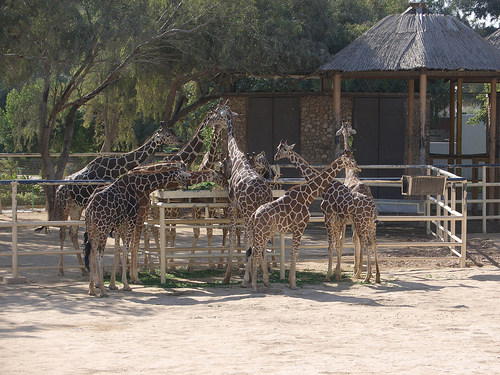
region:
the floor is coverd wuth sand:
[310, 304, 410, 349]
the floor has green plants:
[161, 248, 243, 288]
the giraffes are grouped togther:
[242, 174, 331, 221]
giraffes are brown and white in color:
[215, 162, 362, 225]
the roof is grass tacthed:
[398, 11, 465, 58]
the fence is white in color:
[405, 174, 465, 259]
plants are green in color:
[94, 21, 188, 82]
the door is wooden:
[362, 107, 410, 162]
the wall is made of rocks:
[307, 99, 339, 134]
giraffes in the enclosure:
[30, 124, 407, 299]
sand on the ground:
[185, 318, 346, 360]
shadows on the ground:
[0, 260, 90, 345]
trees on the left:
[9, 12, 190, 124]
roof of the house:
[330, 0, 463, 67]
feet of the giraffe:
[318, 265, 378, 285]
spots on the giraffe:
[331, 197, 362, 222]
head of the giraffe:
[315, 108, 365, 146]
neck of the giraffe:
[225, 127, 252, 168]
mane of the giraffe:
[130, 163, 178, 173]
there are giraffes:
[40, 90, 431, 305]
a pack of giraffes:
[50, 82, 424, 307]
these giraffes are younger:
[245, 119, 380, 290]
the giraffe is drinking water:
[73, 152, 208, 315]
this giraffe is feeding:
[188, 82, 296, 287]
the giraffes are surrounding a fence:
[27, 64, 448, 334]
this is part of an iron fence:
[362, 154, 479, 269]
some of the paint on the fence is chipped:
[4, 168, 120, 205]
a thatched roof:
[325, 3, 499, 75]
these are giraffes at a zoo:
[47, 71, 446, 301]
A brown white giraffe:
[92, 150, 201, 292]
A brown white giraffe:
[250, 137, 375, 279]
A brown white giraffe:
[210, 106, 267, 213]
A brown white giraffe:
[61, 103, 183, 195]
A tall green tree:
[10, 3, 106, 182]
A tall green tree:
[165, 0, 310, 85]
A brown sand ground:
[374, 273, 452, 373]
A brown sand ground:
[219, 292, 319, 347]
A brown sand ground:
[33, 299, 157, 356]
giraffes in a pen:
[12, 21, 482, 333]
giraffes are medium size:
[243, 116, 393, 293]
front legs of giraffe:
[287, 231, 304, 293]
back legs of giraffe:
[247, 235, 272, 292]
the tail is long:
[243, 210, 258, 264]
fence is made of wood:
[368, 159, 494, 266]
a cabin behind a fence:
[198, 3, 491, 246]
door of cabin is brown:
[343, 88, 415, 176]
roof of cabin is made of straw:
[311, 0, 497, 85]